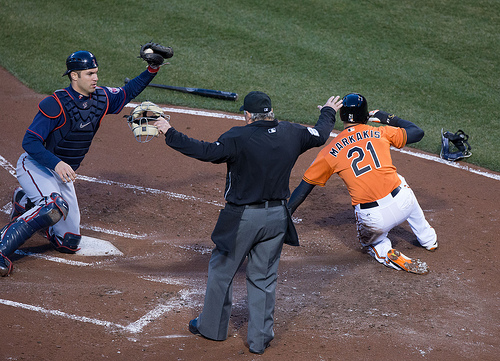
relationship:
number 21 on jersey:
[348, 138, 382, 180] [303, 122, 408, 206]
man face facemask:
[153, 90, 342, 355] [124, 98, 172, 144]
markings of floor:
[31, 250, 188, 340] [45, 268, 180, 351]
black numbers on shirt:
[347, 137, 382, 182] [299, 122, 407, 205]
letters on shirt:
[325, 131, 378, 141] [313, 125, 418, 202]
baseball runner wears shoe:
[287, 93, 440, 276] [366, 232, 438, 282]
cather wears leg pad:
[0, 44, 173, 277] [1, 193, 70, 277]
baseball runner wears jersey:
[287, 93, 440, 276] [304, 119, 410, 201]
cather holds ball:
[3, 44, 177, 249] [143, 43, 153, 53]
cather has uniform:
[0, 44, 173, 277] [33, 95, 91, 167]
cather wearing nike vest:
[0, 44, 173, 277] [45, 87, 107, 174]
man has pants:
[153, 90, 342, 355] [198, 204, 289, 351]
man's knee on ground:
[355, 228, 392, 253] [2, 21, 484, 354]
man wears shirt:
[153, 90, 342, 355] [155, 104, 344, 211]